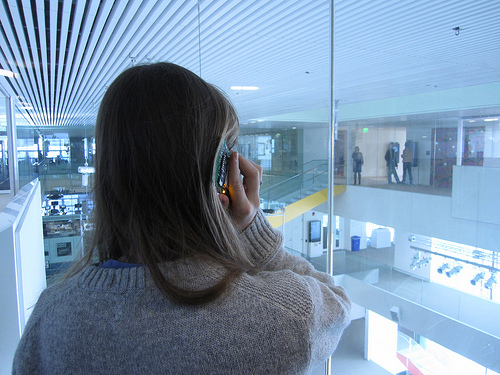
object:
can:
[349, 234, 363, 251]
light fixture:
[406, 251, 419, 271]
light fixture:
[469, 269, 484, 285]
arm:
[236, 219, 351, 344]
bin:
[348, 233, 365, 250]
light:
[228, 84, 262, 94]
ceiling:
[0, 0, 499, 126]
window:
[328, 247, 498, 339]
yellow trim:
[265, 183, 349, 227]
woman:
[349, 146, 364, 186]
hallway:
[267, 167, 458, 200]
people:
[399, 138, 415, 184]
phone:
[211, 137, 240, 193]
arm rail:
[268, 163, 347, 212]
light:
[413, 257, 426, 271]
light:
[443, 265, 462, 281]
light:
[481, 275, 494, 292]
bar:
[405, 242, 499, 273]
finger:
[224, 146, 249, 211]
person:
[10, 59, 353, 374]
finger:
[237, 156, 261, 193]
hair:
[22, 60, 262, 315]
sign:
[307, 217, 320, 243]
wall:
[303, 211, 325, 261]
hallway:
[300, 245, 498, 361]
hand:
[212, 147, 262, 234]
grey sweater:
[10, 211, 350, 374]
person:
[382, 140, 401, 186]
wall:
[345, 126, 411, 176]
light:
[220, 187, 230, 196]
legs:
[356, 169, 362, 183]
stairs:
[256, 173, 342, 216]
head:
[86, 62, 243, 269]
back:
[21, 251, 314, 374]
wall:
[349, 216, 368, 251]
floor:
[293, 245, 498, 337]